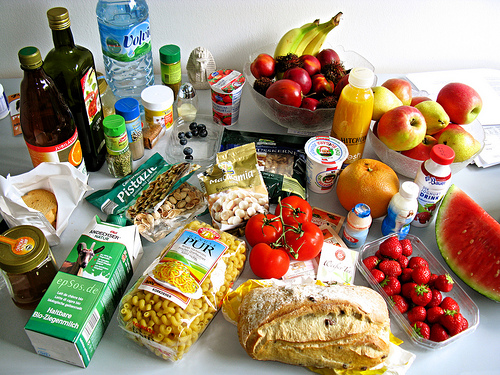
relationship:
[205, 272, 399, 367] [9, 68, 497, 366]
bread on table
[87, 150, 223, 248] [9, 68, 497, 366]
bag on table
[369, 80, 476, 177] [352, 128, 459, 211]
apples are on bin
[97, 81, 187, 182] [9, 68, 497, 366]
spices are on table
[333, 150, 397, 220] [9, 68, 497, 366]
orange on table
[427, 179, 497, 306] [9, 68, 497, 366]
watermelon on table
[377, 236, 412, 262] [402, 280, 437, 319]
strawberry next to strawberry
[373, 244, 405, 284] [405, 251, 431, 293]
strawberry next to strawberry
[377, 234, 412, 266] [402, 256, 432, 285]
strawberry next to strawberry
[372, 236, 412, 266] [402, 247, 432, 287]
strawberry next to strawberry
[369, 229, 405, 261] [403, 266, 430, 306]
strawberry next to strawberry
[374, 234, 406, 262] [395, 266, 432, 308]
strawberry next to strawberry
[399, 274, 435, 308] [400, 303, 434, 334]
strawberry next to strawberry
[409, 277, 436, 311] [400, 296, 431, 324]
strawberry next to strawberry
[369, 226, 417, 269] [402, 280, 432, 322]
strawberry next to strawberry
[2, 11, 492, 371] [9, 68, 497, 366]
food on table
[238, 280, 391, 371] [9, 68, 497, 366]
bread on table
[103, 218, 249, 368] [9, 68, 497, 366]
bag on table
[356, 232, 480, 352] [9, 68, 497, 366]
carton on table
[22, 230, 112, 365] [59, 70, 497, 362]
milk on table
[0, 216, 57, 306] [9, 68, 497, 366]
honey jar on table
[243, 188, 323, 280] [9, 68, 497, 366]
tomatoes on table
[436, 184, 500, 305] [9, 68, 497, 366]
watermelon on table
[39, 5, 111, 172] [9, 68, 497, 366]
olive oil on table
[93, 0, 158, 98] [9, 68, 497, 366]
water bottle on table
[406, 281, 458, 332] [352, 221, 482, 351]
strawberries in carton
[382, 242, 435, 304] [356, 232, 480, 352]
strawberries in carton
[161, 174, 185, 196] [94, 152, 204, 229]
pistachio nuts in bag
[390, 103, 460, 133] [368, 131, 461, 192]
apples in bowl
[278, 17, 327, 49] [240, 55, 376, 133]
bananas in bowl